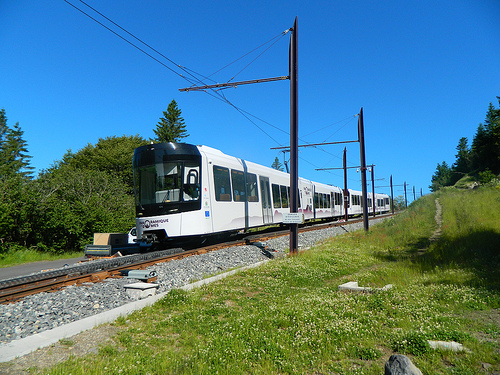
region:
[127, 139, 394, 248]
this is a white train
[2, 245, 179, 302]
these are the train tracks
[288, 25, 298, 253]
this is a telephone post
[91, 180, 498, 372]
this is green grass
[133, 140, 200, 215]
this is a window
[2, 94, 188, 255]
these are green trees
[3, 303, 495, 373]
this is the ground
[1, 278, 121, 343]
these are gray rocks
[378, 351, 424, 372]
this is small log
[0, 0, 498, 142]
this is the clear blue sky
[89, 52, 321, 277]
a train on the tracks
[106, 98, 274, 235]
a window on a train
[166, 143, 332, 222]
the side window of a train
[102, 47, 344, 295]
a train rolling on train tracks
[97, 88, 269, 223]
a train near trees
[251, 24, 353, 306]
a pole near a train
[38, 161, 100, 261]
trees with green leaves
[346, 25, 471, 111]
a clear blue sky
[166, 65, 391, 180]
power lines near a train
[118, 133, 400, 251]
train on the track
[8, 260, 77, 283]
track where train travels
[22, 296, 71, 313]
gravel next to tracks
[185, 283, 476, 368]
field next to tracks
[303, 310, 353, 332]
wild flowers in field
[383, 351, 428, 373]
rock on the ground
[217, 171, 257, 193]
windows on the train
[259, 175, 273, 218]
doors on the train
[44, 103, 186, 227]
trees to the side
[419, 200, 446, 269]
bare strip of land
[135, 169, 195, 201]
The wind sheild of the train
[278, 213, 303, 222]
The sign on the post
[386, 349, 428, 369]
The big rock on the ground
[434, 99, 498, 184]
The trees on the far right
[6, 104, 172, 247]
The group of trees behind the train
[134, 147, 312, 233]
The first car of the white train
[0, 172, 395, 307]
The pebbles along side the rail road tracks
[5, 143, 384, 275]
The rusty rail road tracks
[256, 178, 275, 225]
The door on the first car of the train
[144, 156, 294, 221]
white light rail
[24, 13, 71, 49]
white clouds in blue sky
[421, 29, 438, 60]
white clouds in blue sky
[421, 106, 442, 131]
white clouds in blue sky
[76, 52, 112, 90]
white clouds in blue sky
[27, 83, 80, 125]
white clouds in blue sky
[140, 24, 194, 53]
white clouds in blue sky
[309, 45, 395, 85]
white clouds in blue sky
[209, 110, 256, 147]
white clouds in blue sky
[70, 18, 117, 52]
white clouds in blue sky